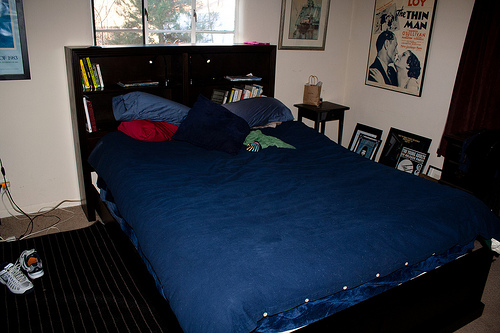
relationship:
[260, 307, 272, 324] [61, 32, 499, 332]
stud on bed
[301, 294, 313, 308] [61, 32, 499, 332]
stud on bed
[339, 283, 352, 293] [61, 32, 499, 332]
stud on bed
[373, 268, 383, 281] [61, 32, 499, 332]
stud on bed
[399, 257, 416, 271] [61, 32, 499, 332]
stud on bed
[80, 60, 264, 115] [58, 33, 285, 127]
books on bed head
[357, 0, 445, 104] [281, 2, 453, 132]
poster on wall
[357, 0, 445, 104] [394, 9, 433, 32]
poster of movie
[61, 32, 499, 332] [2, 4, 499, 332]
bed in bedroom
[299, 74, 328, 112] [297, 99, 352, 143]
bag on night tabl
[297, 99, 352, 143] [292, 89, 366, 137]
night table on corner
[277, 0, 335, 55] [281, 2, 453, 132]
picture on wall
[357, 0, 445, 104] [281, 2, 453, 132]
poster hold in wall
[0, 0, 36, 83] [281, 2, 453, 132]
pictures leans on wall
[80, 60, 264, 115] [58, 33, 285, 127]
books on bed shelf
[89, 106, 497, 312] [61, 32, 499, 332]
coverlet on bed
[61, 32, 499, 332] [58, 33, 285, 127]
bed has shelves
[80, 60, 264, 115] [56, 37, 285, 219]
books on headboard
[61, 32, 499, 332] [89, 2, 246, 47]
bed front of window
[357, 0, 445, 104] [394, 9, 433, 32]
poster of thin man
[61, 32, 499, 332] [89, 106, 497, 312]
bed cover with duvet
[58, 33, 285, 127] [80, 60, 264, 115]
shelves for books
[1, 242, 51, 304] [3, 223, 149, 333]
tennis shoes on floor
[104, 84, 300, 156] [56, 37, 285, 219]
pillows at head of bed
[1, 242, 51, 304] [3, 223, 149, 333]
sneakers on floor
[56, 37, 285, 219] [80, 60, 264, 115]
shelves of books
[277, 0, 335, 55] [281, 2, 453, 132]
picture against wall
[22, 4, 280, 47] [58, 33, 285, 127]
wall behind shelf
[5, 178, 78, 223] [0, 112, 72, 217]
wire plug into wall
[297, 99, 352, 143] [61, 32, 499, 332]
table side of bed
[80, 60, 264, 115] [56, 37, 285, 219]
books in shelf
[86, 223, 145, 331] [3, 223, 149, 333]
line marking floor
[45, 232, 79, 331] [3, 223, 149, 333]
line marking floor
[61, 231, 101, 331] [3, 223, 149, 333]
line marking floor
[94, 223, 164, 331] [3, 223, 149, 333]
line marking floor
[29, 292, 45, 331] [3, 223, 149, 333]
line marking floor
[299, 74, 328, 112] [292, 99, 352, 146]
bag sitting on top of table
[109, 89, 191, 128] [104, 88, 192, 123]
pillow case covering pillow